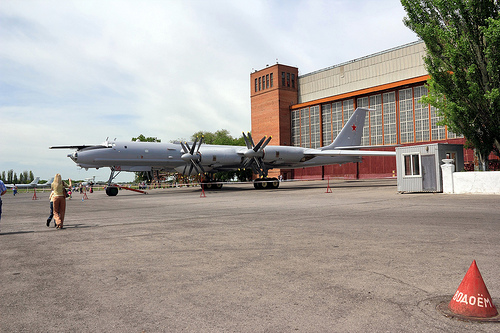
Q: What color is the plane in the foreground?
A: Grey.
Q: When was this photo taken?
A: Daytime.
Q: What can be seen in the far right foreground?
A: A cone.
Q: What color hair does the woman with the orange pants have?
A: Blonde.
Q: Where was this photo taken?
A: An airport.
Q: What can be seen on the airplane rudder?
A: A star.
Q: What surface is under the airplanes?
A: Pavement.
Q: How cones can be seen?
A: One.